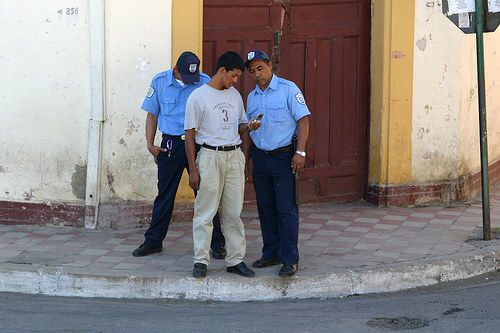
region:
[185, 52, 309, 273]
Two men looking at a cell phone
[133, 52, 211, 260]
Policeman staring at the ground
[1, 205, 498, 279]
A tiled sidewalk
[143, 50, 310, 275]
A man and two policeman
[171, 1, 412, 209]
Wooden double doors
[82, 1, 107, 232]
A broken gutter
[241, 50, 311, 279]
A policeman looking at a cellphone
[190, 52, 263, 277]
A man showing off his cellphone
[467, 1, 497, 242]
A crooked lightpole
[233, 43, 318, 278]
Man wearing a blue shirt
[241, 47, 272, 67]
Hat on the man's head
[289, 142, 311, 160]
Watch on the man's wrist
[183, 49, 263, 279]
Man wearing a gray shirt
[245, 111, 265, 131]
Phone in the man's hand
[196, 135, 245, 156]
Belt around the man's waist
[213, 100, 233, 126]
Number on the man's shirt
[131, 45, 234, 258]
Man wearing a blue shirt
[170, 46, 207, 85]
Hat on the man's head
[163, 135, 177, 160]
Keychain on man's pants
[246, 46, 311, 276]
Man wearing police uniform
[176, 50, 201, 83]
A blue police cap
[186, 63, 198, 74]
White budge on blue cap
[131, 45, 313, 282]
Three men standing on pavement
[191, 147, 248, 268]
Man wearing beige pants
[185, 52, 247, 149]
Man wearing gray t-shirt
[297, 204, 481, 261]
Red and white tiles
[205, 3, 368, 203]
Brown door on building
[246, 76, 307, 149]
A blue police shirt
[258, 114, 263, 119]
A cell phone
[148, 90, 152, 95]
A badge on the shoulder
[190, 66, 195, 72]
A badge on the cap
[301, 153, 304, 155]
A watch on the wrist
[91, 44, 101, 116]
A drain pipe on the wall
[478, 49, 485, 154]
A pole in the ground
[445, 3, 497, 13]
A traffic sign board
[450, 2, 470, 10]
Paper posted on sign board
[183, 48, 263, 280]
man wearing grey shirt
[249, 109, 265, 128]
man holding cell phone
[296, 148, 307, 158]
officer wearing silver watch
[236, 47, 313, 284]
police officer looking at phone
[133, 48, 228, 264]
officer standing behind man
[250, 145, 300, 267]
officer wearing dark blue pants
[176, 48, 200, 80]
officer wearing blue hat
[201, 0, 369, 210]
brown wooden doors behind men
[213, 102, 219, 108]
print letter on shirt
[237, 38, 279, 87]
the head of a man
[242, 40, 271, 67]
the hat of a man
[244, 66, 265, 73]
the eyes of a man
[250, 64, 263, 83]
the nose of a man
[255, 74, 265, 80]
the mouth of a man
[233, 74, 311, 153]
the shirt of a man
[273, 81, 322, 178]
the arm of a man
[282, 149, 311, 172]
the hand of a man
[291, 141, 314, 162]
the watch of a man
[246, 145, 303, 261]
the pants of a man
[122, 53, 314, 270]
the men are standing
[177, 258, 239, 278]
shoes on the feet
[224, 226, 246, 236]
the pants are tan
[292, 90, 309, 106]
badge on the sleeve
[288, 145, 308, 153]
watch on the wrist